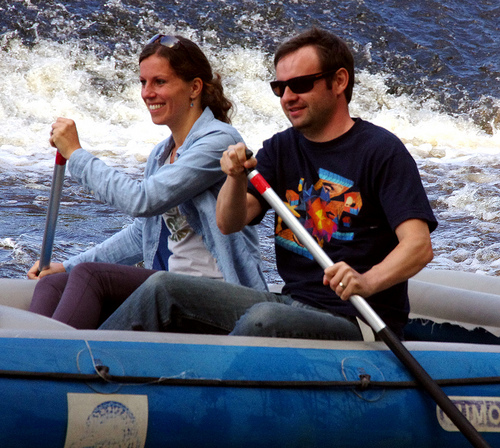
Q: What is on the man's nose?
A: His sunglasses.